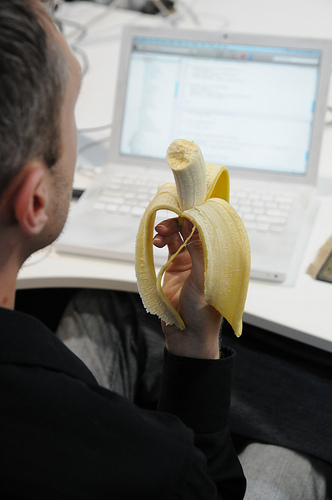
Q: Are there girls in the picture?
A: No, there are no girls.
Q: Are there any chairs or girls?
A: No, there are no girls or chairs.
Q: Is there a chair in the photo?
A: No, there are no chairs.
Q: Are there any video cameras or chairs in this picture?
A: No, there are no chairs or video cameras.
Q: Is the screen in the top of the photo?
A: Yes, the screen is in the top of the image.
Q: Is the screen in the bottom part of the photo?
A: No, the screen is in the top of the image.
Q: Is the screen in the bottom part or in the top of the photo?
A: The screen is in the top of the image.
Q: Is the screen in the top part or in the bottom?
A: The screen is in the top of the image.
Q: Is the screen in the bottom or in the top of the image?
A: The screen is in the top of the image.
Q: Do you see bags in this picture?
A: No, there are no bags.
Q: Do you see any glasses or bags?
A: No, there are no bags or glasses.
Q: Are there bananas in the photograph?
A: Yes, there is a banana.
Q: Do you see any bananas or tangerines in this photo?
A: Yes, there is a banana.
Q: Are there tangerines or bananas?
A: Yes, there is a banana.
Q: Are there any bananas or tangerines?
A: Yes, there is a banana.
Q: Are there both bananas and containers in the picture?
A: No, there is a banana but no containers.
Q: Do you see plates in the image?
A: No, there are no plates.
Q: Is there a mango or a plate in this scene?
A: No, there are no plates or mangoes.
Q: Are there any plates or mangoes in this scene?
A: No, there are no plates or mangoes.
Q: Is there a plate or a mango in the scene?
A: No, there are no plates or mangoes.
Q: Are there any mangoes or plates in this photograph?
A: No, there are no plates or mangoes.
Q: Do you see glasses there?
A: No, there are no glasses.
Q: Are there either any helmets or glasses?
A: No, there are no glasses or helmets.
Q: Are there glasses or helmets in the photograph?
A: No, there are no glasses or helmets.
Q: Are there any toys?
A: No, there are no toys.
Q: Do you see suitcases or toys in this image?
A: No, there are no toys or suitcases.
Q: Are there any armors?
A: No, there are no armors.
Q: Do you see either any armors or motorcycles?
A: No, there are no armors or motorcycles.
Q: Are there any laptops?
A: Yes, there is a laptop.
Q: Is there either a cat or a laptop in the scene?
A: Yes, there is a laptop.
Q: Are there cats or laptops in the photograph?
A: Yes, there is a laptop.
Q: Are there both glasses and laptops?
A: No, there is a laptop but no glasses.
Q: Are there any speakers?
A: No, there are no speakers.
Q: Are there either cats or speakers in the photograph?
A: No, there are no speakers or cats.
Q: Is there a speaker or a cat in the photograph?
A: No, there are no speakers or cats.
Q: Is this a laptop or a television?
A: This is a laptop.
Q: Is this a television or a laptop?
A: This is a laptop.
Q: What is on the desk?
A: The laptop is on the desk.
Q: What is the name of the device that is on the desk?
A: The device is a laptop.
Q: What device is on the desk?
A: The device is a laptop.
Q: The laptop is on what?
A: The laptop is on the desk.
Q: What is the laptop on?
A: The laptop is on the desk.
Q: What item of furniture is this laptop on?
A: The laptop is on the desk.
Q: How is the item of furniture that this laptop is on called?
A: The piece of furniture is a desk.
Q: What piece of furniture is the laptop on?
A: The laptop is on the desk.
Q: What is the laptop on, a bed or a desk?
A: The laptop is on a desk.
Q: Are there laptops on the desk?
A: Yes, there is a laptop on the desk.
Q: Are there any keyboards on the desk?
A: No, there is a laptop on the desk.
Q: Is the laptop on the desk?
A: Yes, the laptop is on the desk.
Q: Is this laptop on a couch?
A: No, the laptop is on the desk.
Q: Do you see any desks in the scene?
A: Yes, there is a desk.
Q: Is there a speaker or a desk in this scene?
A: Yes, there is a desk.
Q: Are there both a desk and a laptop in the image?
A: Yes, there are both a desk and a laptop.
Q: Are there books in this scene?
A: No, there are no books.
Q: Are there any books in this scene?
A: No, there are no books.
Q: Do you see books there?
A: No, there are no books.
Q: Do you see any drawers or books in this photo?
A: No, there are no books or drawers.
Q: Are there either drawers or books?
A: No, there are no books or drawers.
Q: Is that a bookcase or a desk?
A: That is a desk.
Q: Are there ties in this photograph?
A: No, there are no ties.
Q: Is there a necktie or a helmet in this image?
A: No, there are no ties or helmets.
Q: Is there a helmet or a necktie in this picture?
A: No, there are no ties or helmets.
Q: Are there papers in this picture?
A: No, there are no papers.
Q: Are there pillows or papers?
A: No, there are no papers or pillows.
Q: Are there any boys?
A: No, there are no boys.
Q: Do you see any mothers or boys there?
A: No, there are no boys or mothers.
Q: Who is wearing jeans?
A: The gentleman is wearing jeans.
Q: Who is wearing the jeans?
A: The gentleman is wearing jeans.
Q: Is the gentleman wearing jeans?
A: Yes, the gentleman is wearing jeans.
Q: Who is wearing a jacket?
A: The gentleman is wearing a jacket.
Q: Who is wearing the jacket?
A: The gentleman is wearing a jacket.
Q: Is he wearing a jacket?
A: Yes, the gentleman is wearing a jacket.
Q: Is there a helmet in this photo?
A: No, there are no helmets.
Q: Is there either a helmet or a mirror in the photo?
A: No, there are no helmets or mirrors.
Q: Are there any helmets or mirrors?
A: No, there are no helmets or mirrors.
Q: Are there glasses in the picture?
A: No, there are no glasses.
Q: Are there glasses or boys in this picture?
A: No, there are no glasses or boys.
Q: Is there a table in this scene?
A: Yes, there is a table.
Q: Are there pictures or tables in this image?
A: Yes, there is a table.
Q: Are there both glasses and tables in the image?
A: No, there is a table but no glasses.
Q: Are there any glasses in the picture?
A: No, there are no glasses.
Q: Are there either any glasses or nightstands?
A: No, there are no glasses or nightstands.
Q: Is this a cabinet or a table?
A: This is a table.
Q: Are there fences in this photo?
A: No, there are no fences.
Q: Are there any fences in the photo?
A: No, there are no fences.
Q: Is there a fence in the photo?
A: No, there are no fences.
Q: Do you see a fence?
A: No, there are no fences.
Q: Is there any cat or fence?
A: No, there are no fences or cats.